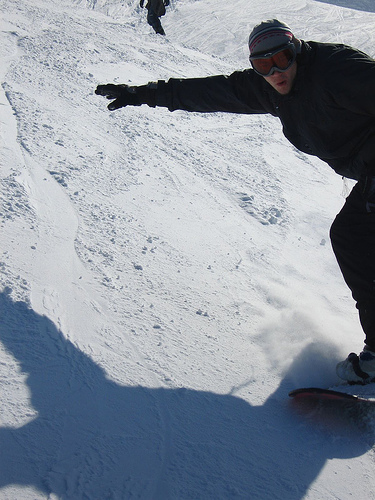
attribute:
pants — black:
[328, 177, 374, 353]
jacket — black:
[138, 37, 374, 197]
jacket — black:
[291, 80, 355, 162]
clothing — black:
[218, 65, 363, 221]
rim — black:
[276, 376, 373, 408]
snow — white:
[38, 150, 369, 391]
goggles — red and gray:
[250, 41, 295, 71]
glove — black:
[93, 82, 154, 113]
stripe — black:
[249, 23, 285, 48]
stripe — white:
[249, 24, 291, 43]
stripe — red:
[244, 28, 297, 42]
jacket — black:
[162, 67, 368, 174]